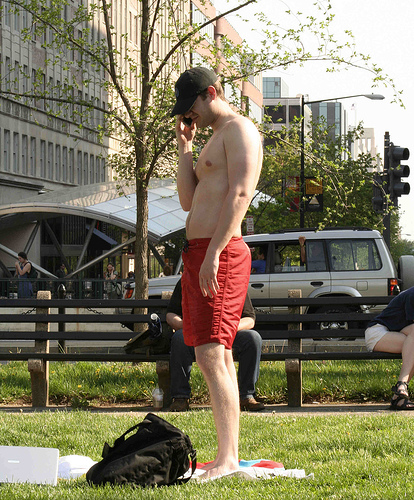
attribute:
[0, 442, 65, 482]
laptop — gray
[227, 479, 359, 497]
grass — green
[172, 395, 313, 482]
feet — man's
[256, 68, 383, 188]
buildings — few, tall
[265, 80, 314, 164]
building — tall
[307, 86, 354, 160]
building — tall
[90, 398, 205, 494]
bag — plain, black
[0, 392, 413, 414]
sidewalk — concrete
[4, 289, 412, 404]
bench — wooden, stone, long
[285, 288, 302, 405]
support — concrete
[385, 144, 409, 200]
light — traffic, black, metal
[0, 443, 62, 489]
laptop — silver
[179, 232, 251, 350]
shorts — bright red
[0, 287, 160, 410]
bench — wooden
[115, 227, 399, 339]
suv — large, silver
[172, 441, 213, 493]
strap — black 